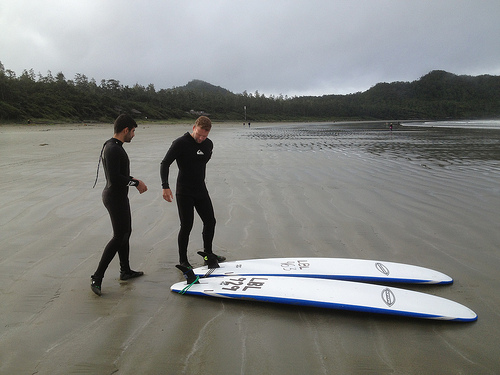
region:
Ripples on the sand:
[449, 130, 483, 161]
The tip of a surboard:
[443, 298, 480, 322]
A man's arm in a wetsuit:
[161, 143, 173, 189]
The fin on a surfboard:
[180, 260, 197, 286]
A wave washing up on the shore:
[398, 119, 433, 129]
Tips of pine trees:
[59, 75, 99, 86]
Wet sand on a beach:
[103, 326, 194, 363]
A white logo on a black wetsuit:
[192, 142, 204, 157]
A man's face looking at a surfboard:
[188, 119, 214, 141]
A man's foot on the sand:
[90, 274, 105, 295]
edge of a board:
[263, 277, 290, 304]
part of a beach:
[199, 306, 227, 336]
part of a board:
[336, 293, 359, 320]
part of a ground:
[179, 349, 202, 367]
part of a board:
[293, 278, 324, 318]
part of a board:
[322, 256, 341, 283]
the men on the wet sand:
[90, 111, 226, 293]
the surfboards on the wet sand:
[170, 257, 477, 321]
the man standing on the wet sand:
[161, 115, 226, 270]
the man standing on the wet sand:
[89, 112, 146, 294]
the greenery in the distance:
[1, 61, 498, 123]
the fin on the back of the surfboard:
[176, 264, 200, 284]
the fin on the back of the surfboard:
[197, 250, 217, 268]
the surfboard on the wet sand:
[169, 275, 478, 337]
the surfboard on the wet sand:
[186, 250, 453, 285]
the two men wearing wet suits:
[90, 110, 227, 295]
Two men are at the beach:
[26, 52, 482, 348]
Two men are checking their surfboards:
[53, 72, 473, 367]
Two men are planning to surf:
[45, 40, 497, 361]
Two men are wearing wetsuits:
[28, 80, 478, 356]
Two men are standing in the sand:
[45, 72, 483, 362]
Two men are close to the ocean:
[42, 43, 483, 364]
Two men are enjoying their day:
[36, 60, 481, 355]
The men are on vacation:
[48, 48, 469, 360]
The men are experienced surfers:
[68, 96, 483, 346]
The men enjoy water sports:
[34, 76, 484, 351]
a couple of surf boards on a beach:
[169, 251, 481, 323]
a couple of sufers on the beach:
[79, 112, 226, 307]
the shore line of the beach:
[263, 106, 438, 198]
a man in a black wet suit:
[80, 136, 145, 301]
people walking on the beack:
[240, 117, 255, 129]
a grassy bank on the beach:
[8, 80, 155, 145]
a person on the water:
[387, 118, 397, 139]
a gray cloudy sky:
[39, 2, 384, 71]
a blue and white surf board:
[205, 281, 459, 311]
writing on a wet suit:
[192, 146, 209, 167]